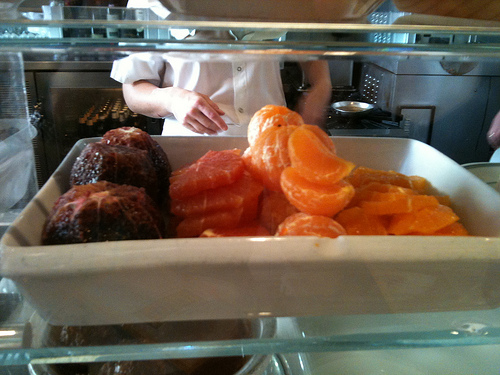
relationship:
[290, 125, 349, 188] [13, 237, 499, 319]
wedge inside of pan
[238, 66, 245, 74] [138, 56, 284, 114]
button sewn onto shirt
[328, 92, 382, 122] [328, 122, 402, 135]
frying pan on top of stove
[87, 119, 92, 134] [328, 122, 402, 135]
bottle next to stove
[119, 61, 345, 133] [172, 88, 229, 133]
person has hand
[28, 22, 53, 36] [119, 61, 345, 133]
bag behind person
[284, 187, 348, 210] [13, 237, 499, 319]
slice inside of pan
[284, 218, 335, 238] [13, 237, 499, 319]
slice in pan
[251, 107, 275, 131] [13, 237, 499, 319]
slice inside pan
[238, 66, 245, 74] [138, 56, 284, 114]
button sewn on shirt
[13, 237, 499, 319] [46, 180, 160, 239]
pan with fruit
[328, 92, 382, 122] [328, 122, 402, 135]
frying pan sitting on stove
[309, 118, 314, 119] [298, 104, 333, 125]
ring on hand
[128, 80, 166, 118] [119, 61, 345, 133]
arm of person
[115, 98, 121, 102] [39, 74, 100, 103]
bottle inside of fridge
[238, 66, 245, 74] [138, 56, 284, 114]
button on shirt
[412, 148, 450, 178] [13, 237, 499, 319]
light reflecting on pan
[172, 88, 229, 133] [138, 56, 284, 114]
hand in front of shirt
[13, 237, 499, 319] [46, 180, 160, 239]
pan of fruit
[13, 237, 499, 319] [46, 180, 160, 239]
pan holding fruit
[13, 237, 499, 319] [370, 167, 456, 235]
pan with orange